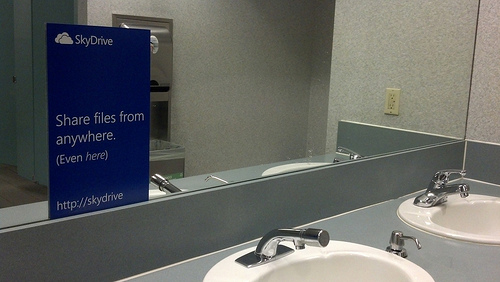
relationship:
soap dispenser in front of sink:
[384, 230, 422, 257] [202, 235, 434, 282]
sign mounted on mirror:
[45, 21, 152, 219] [0, 0, 480, 230]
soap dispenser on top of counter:
[384, 230, 422, 257] [116, 176, 500, 282]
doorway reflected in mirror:
[2, 1, 14, 176] [0, 0, 480, 230]